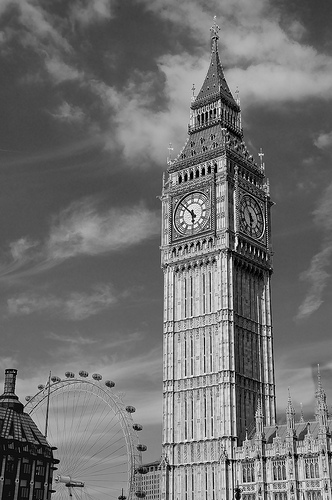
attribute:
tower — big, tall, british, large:
[156, 14, 278, 499]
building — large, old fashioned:
[155, 14, 331, 499]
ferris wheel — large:
[24, 370, 148, 499]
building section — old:
[234, 363, 331, 499]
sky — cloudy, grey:
[0, 1, 331, 500]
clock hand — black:
[179, 202, 197, 218]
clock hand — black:
[190, 209, 194, 224]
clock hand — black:
[244, 197, 254, 222]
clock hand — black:
[249, 214, 253, 227]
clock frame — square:
[168, 181, 216, 247]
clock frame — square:
[238, 186, 268, 247]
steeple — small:
[253, 388, 265, 433]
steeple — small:
[285, 386, 297, 428]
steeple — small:
[313, 363, 329, 427]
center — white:
[54, 473, 72, 484]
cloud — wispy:
[1, 190, 162, 291]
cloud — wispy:
[0, 280, 163, 322]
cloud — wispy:
[291, 235, 331, 323]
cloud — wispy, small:
[308, 127, 331, 151]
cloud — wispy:
[0, 0, 331, 172]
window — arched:
[242, 467, 247, 483]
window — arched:
[246, 467, 251, 484]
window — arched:
[250, 467, 255, 482]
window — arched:
[273, 465, 278, 480]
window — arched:
[277, 464, 282, 480]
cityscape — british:
[0, 14, 331, 499]